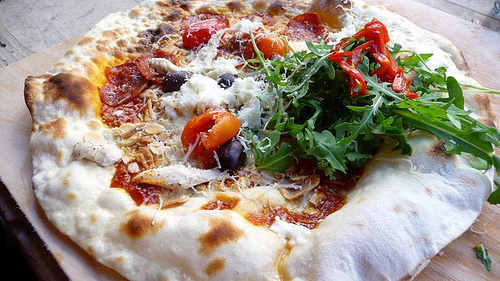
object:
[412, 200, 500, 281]
ground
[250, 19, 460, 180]
topping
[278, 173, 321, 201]
topping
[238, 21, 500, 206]
green vegetable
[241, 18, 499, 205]
argula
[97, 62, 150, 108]
meat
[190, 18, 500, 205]
truck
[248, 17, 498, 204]
vegetable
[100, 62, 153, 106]
topping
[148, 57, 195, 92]
topping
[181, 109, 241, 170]
topping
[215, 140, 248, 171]
topping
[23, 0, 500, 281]
baked pizza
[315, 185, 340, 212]
sauce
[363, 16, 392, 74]
pepper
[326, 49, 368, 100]
pepper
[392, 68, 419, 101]
pepper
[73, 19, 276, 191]
cheese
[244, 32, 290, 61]
topping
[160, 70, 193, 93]
olives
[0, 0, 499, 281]
table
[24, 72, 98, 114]
burnt end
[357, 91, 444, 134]
leafs